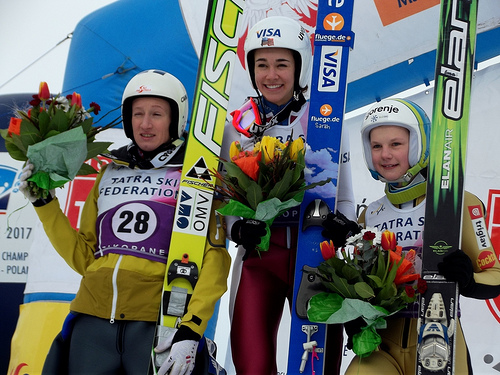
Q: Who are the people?
A: Athletes.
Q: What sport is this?
A: Skiing.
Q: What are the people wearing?
A: Helmets.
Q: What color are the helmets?
A: White.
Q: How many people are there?
A: Three.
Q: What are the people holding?
A: Flowers.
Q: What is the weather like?
A: Cold.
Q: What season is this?
A: Winter.